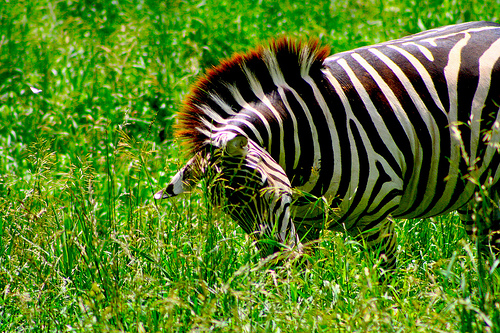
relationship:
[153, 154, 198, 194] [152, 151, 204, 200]
edge of ear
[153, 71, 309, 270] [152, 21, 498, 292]
head of zebra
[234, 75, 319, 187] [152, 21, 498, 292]
neck of zebra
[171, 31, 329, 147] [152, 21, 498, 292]
mane of zebra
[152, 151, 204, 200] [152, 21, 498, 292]
ear of zebra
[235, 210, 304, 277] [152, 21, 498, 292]
nose of zebra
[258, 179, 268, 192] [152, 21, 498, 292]
eye of zebra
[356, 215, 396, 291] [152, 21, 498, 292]
leg of zebra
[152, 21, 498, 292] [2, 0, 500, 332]
zebra in grass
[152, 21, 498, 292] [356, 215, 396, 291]
zebra has leg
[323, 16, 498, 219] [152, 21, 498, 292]
body of zebra